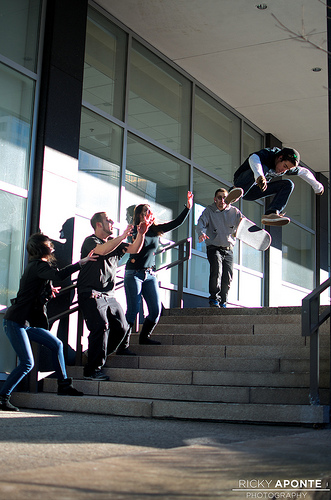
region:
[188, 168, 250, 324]
A person standing on a stair case.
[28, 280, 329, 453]
a stair case in a hall.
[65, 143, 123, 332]
a window on a building.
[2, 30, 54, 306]
a glass door on a building.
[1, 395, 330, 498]
a paved area of sidewalk.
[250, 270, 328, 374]
a rail near of some stairs.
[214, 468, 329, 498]
a water mark on a picture.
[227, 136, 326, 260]
a man on a skateboard.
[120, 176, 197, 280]
a sweater on a young girl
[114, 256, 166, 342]
a pair of tight jeans.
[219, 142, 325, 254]
a skateboarder doing tricks on a skateboard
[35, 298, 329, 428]
concret stairs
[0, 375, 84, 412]
a pair of woman's ankle boots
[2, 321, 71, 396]
a pair of blue jeans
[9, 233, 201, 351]
a metal hand rail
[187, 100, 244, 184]
a top glass window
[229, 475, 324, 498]
the name of the company who took the photo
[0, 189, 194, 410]
people watching a skateboarder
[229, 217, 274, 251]
a black skateboard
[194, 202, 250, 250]
a grey sweatshirt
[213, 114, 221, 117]
part of a window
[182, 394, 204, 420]
part of a stair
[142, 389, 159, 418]
edge of a stair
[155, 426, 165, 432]
part of a shadow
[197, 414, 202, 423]
edge of a stair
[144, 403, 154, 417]
side of a stair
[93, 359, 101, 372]
part of a jeans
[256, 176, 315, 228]
Person wearing blue jeans.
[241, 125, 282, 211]
Person wearing white long sleeved shirt.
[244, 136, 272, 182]
Person wearing black t-shirt over white shirt.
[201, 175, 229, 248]
Person wearing gray hoodie.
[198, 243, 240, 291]
Person wearing dark pants.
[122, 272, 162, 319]
Person wearing jeans.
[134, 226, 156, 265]
Person wearing black shirt.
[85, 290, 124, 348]
Person wearing black pants.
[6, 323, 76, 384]
Person wearing blue jeans.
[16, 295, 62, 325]
Person wearing black shirt.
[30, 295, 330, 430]
cement stairs outside of a building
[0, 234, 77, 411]
a woman wearing a black sweatshirt and jeans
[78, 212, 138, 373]
a man dressed in black reaching up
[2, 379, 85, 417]
black shoes on the ground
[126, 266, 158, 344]
woman wearing blue jeans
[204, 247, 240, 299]
black jeans on a man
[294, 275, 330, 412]
railing on the cement steps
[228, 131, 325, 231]
a skateboarder in the air doing a jump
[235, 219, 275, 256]
skateboard in the air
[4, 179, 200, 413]
three people standing on the stairs